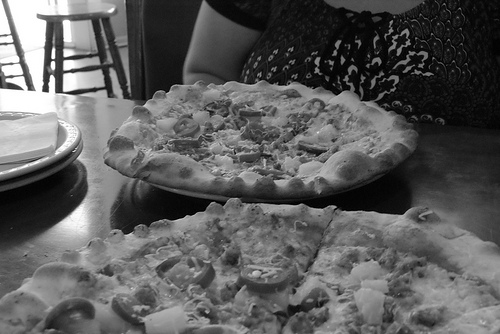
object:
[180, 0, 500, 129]
lady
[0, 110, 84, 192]
white plate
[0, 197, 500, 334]
pizza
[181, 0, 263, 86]
light skinned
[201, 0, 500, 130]
blouse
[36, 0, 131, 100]
chair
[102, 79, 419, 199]
pizza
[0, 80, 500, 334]
table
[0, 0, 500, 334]
kitchen